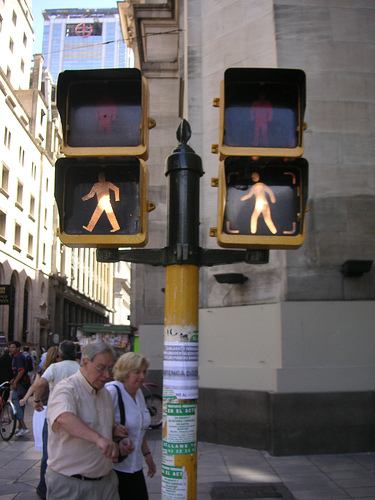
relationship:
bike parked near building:
[0, 380, 17, 442] [1, 2, 116, 338]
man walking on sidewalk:
[45, 340, 136, 499] [0, 422, 374, 498]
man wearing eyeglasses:
[45, 340, 115, 496] [89, 360, 114, 372]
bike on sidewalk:
[1, 380, 17, 442] [0, 435, 373, 499]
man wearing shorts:
[4, 335, 37, 438] [9, 378, 32, 420]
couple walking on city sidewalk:
[46, 339, 156, 498] [0, 397, 373, 498]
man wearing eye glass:
[45, 340, 136, 499] [89, 355, 113, 376]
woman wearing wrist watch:
[107, 351, 157, 498] [142, 450, 152, 457]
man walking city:
[45, 340, 136, 499] [1, 2, 373, 495]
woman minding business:
[102, 351, 157, 499] [0, 325, 156, 492]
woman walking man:
[102, 351, 157, 499] [44, 344, 135, 490]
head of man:
[81, 342, 118, 370] [42, 339, 122, 499]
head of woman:
[111, 352, 147, 392] [106, 343, 159, 498]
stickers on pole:
[164, 347, 196, 396] [161, 264, 194, 498]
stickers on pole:
[166, 404, 194, 439] [161, 264, 194, 498]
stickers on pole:
[163, 442, 195, 454] [161, 264, 194, 498]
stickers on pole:
[163, 468, 184, 499] [161, 264, 194, 498]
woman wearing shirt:
[102, 351, 157, 499] [102, 378, 150, 472]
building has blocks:
[186, 5, 374, 65] [272, 19, 362, 92]